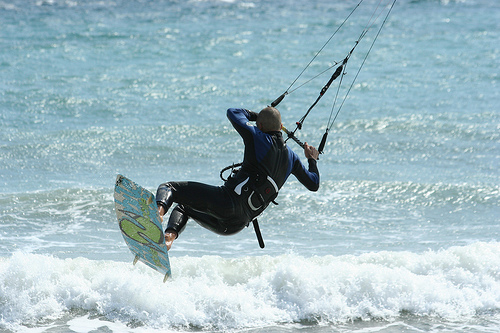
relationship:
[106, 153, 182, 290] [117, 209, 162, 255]
board has on it a designs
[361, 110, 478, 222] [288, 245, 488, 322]
water making a wave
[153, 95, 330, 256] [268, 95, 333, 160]
man hanging onto handle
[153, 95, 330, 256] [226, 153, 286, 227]
man wearing a harness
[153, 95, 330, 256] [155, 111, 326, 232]
man has on a wetsuit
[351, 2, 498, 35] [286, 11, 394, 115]
kite attached by a string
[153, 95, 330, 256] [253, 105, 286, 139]
man has a head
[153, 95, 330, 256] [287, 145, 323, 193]
man has an arm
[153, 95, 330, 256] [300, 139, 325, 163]
man has a hand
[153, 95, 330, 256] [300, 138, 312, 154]
man has a thumb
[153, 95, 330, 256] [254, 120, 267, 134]
man has an ear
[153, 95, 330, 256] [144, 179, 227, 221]
man has a leg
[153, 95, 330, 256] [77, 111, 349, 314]
parasailer in mid air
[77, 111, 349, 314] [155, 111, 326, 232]
parasailer wearing a wetsuit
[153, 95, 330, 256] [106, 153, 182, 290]
parasailer on top of board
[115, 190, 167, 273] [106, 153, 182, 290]
designs are on bottom of board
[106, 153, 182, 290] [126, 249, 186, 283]
board has fins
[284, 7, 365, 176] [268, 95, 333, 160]
parasail has a handle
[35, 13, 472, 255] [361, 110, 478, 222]
ocean full of water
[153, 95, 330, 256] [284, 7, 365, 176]
man holding parasail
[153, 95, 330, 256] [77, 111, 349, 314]
man up in air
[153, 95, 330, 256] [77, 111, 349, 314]
parasailer in air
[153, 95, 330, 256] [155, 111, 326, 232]
parasailer wearing a wetsuit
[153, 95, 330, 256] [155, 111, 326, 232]
parasailer has on a wetsuit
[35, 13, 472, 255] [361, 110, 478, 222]
body compred of water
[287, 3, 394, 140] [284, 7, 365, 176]
chords on parasail